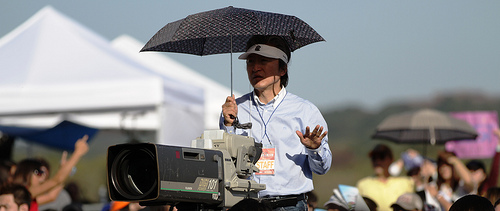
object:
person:
[220, 43, 332, 210]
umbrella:
[138, 6, 327, 130]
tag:
[253, 148, 275, 174]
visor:
[238, 43, 291, 66]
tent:
[0, 6, 249, 151]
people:
[0, 135, 96, 210]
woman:
[0, 134, 91, 211]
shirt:
[219, 84, 332, 198]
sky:
[0, 1, 499, 115]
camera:
[105, 134, 265, 210]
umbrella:
[369, 107, 479, 162]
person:
[353, 144, 416, 210]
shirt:
[357, 175, 414, 210]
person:
[438, 148, 499, 197]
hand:
[295, 124, 329, 148]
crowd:
[353, 142, 499, 210]